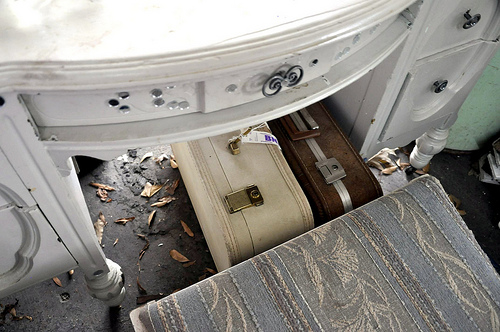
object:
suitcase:
[172, 126, 314, 273]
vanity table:
[0, 0, 498, 141]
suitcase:
[271, 101, 390, 217]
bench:
[130, 175, 500, 330]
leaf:
[171, 248, 187, 261]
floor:
[123, 242, 187, 288]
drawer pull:
[438, 75, 449, 94]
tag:
[242, 130, 277, 145]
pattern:
[312, 249, 365, 314]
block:
[478, 154, 493, 185]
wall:
[461, 78, 497, 153]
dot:
[108, 99, 120, 107]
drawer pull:
[465, 12, 484, 29]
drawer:
[383, 38, 488, 141]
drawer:
[24, 6, 414, 133]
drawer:
[411, 1, 499, 55]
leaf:
[140, 183, 155, 196]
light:
[13, 8, 48, 30]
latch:
[227, 189, 259, 211]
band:
[306, 138, 328, 160]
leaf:
[96, 215, 105, 235]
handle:
[285, 120, 297, 137]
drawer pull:
[267, 70, 309, 95]